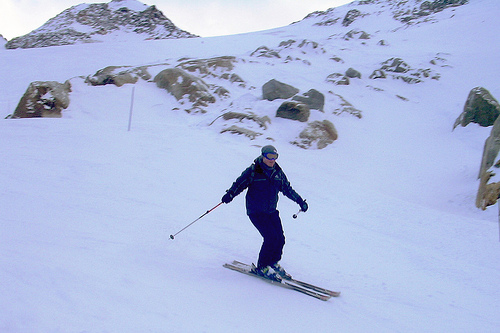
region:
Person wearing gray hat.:
[253, 145, 292, 166]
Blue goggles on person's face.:
[256, 138, 295, 169]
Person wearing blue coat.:
[234, 168, 297, 201]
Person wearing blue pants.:
[246, 208, 314, 253]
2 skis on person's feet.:
[245, 232, 314, 309]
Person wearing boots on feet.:
[246, 253, 306, 285]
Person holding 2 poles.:
[175, 164, 345, 256]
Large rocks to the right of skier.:
[456, 97, 498, 187]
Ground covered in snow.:
[120, 225, 193, 313]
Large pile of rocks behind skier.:
[187, 62, 367, 132]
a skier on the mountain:
[9, 10, 389, 248]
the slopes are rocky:
[34, 13, 492, 132]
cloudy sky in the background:
[6, 3, 338, 45]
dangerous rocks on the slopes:
[14, 40, 331, 137]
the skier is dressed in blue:
[158, 117, 387, 311]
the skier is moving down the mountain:
[150, 130, 479, 312]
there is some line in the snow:
[98, 53, 153, 147]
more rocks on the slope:
[395, 35, 498, 224]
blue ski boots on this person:
[245, 254, 297, 300]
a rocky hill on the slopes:
[28, 1, 200, 51]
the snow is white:
[174, 299, 210, 321]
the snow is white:
[359, 259, 405, 320]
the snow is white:
[377, 262, 397, 330]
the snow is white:
[391, 286, 416, 331]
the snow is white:
[391, 213, 423, 305]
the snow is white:
[402, 214, 418, 264]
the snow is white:
[384, 263, 418, 315]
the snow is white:
[339, 321, 348, 330]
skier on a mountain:
[164, 128, 354, 311]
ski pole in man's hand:
[159, 200, 230, 247]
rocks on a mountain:
[4, 65, 76, 128]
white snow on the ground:
[21, 170, 144, 318]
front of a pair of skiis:
[300, 268, 349, 311]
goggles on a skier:
[264, 150, 281, 165]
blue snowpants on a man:
[246, 215, 297, 270]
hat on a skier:
[262, 140, 278, 150]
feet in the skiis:
[250, 260, 297, 282]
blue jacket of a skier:
[220, 160, 310, 215]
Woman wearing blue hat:
[258, 143, 281, 155]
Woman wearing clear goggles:
[261, 153, 283, 160]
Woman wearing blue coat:
[260, 192, 276, 207]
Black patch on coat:
[253, 168, 266, 182]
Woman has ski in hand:
[213, 182, 239, 216]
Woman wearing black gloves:
[220, 190, 235, 207]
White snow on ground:
[349, 200, 419, 282]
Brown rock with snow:
[8, 58, 77, 145]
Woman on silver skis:
[166, 137, 350, 326]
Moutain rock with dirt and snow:
[32, 7, 187, 52]